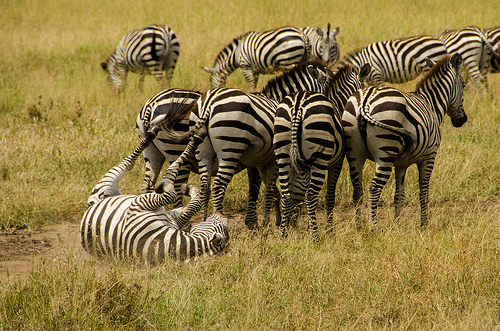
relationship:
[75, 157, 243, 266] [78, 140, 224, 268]
zebra falling over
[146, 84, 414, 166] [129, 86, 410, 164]
four zebra butts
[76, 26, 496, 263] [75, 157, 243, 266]
herd a zebra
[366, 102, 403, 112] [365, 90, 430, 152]
black white stripes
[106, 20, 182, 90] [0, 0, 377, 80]
zebra grazing background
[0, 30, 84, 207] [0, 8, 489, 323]
grass of safari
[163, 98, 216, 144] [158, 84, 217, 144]
zebra's tail zebra's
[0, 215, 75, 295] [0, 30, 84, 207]
dirt between grass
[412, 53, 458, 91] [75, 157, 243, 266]
mane of zebra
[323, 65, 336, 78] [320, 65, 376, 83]
perked up ears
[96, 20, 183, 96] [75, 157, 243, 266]
zebra farthest zebra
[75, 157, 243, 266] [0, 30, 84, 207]
zebra lying grass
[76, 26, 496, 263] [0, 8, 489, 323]
herd of zebras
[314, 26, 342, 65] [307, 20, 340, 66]
face of zebra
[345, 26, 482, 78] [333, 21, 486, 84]
two zebras eating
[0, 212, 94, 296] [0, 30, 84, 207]
dirt without grass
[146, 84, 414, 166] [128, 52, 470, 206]
four zebras together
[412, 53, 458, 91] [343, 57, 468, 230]
mane of zebra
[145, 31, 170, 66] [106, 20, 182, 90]
tail of zebra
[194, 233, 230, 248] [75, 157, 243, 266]
ears of zebra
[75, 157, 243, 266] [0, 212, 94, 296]
zebra on dirt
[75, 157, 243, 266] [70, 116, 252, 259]
zebra fooling around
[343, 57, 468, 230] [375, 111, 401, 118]
zebra black white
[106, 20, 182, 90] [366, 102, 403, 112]
zebra tail black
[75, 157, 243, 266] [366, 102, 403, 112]
zebra hooves black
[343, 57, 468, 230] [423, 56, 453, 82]
zebra mane brown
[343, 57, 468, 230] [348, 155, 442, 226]
zebra four legs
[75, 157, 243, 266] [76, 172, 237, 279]
zebra laying down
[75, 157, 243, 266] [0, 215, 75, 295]
zebra laying dirt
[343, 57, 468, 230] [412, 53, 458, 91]
zebra has mane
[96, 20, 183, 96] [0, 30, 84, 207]
zebra in grass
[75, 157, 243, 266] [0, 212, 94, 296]
zebra laying dirt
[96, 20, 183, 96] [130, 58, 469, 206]
zebra lined up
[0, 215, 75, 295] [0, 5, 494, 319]
dirt path photo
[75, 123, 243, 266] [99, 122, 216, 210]
zebra zebra kicking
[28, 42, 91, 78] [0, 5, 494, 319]
green grass photo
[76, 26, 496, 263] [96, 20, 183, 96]
herd of zebra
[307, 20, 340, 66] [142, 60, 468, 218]
zebra facing others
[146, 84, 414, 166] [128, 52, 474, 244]
four zebras together